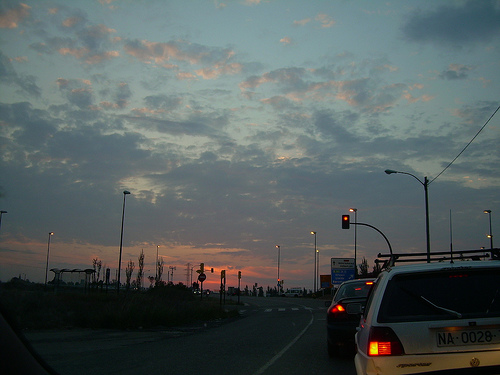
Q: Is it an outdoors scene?
A: Yes, it is outdoors.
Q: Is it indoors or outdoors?
A: It is outdoors.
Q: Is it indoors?
A: No, it is outdoors.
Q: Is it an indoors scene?
A: No, it is outdoors.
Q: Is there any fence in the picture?
A: No, there are no fences.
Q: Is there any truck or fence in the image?
A: No, there are no fences or trucks.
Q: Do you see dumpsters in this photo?
A: No, there are no dumpsters.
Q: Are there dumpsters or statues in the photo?
A: No, there are no dumpsters or statues.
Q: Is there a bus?
A: No, there are no buses.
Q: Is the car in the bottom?
A: Yes, the car is in the bottom of the image.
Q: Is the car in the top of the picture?
A: No, the car is in the bottom of the image.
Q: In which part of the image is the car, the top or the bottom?
A: The car is in the bottom of the image.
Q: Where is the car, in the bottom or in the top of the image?
A: The car is in the bottom of the image.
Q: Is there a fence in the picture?
A: No, there are no fences.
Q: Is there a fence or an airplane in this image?
A: No, there are no fences or airplanes.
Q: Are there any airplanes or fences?
A: No, there are no fences or airplanes.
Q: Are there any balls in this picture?
A: No, there are no balls.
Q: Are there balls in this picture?
A: No, there are no balls.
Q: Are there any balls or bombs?
A: No, there are no balls or bombs.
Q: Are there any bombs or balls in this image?
A: No, there are no balls or bombs.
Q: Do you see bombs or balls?
A: No, there are no balls or bombs.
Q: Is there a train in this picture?
A: No, there are no trains.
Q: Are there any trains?
A: No, there are no trains.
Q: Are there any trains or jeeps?
A: No, there are no trains or jeeps.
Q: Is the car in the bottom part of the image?
A: Yes, the car is in the bottom of the image.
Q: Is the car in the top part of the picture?
A: No, the car is in the bottom of the image.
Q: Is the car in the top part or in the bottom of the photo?
A: The car is in the bottom of the image.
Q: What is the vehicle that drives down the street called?
A: The vehicle is a car.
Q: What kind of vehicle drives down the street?
A: The vehicle is a car.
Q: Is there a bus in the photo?
A: No, there are no buses.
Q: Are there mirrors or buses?
A: No, there are no buses or mirrors.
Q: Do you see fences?
A: No, there are no fences.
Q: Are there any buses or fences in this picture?
A: No, there are no fences or buses.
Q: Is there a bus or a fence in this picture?
A: No, there are no fences or buses.